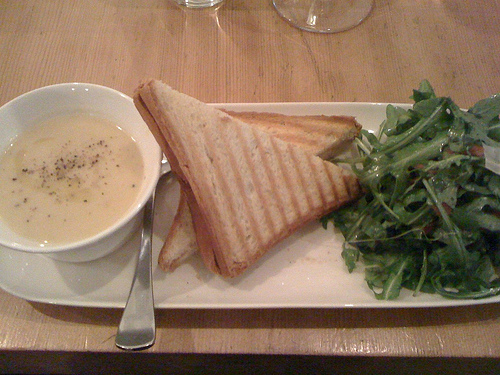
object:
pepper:
[25, 140, 105, 195]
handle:
[114, 183, 157, 350]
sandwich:
[130, 75, 361, 279]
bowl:
[1, 79, 166, 260]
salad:
[322, 77, 500, 300]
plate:
[1, 100, 499, 310]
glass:
[271, 1, 371, 34]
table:
[1, 1, 499, 358]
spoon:
[114, 154, 172, 351]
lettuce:
[346, 81, 498, 304]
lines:
[268, 111, 303, 234]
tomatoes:
[418, 163, 462, 216]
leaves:
[376, 130, 466, 181]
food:
[1, 77, 500, 300]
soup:
[2, 115, 145, 242]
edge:
[2, 348, 500, 374]